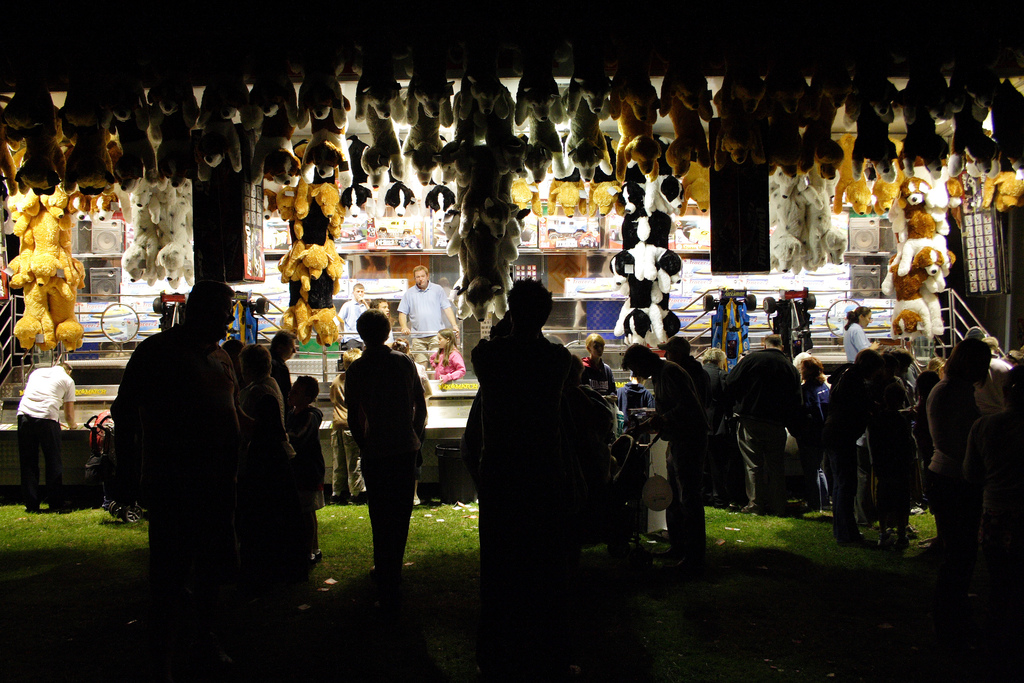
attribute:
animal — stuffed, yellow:
[16, 195, 83, 304]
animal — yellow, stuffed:
[269, 217, 343, 319]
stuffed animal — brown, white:
[888, 168, 953, 244]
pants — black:
[7, 411, 62, 522]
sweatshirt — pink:
[430, 351, 467, 386]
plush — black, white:
[618, 161, 668, 235]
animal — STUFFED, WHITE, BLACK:
[606, 206, 680, 347]